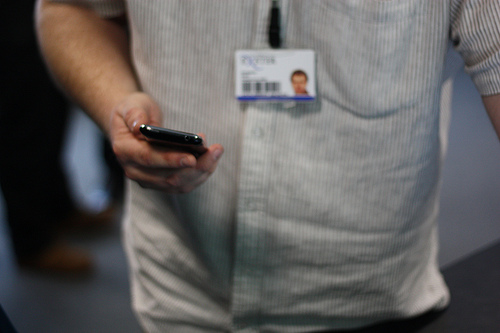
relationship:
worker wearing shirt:
[30, 0, 497, 329] [104, 1, 499, 330]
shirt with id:
[104, 1, 499, 330] [232, 49, 319, 102]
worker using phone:
[30, 0, 497, 329] [149, 90, 194, 171]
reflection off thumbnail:
[148, 107, 204, 133] [126, 118, 142, 133]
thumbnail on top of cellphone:
[126, 118, 142, 133] [125, 118, 210, 165]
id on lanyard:
[232, 49, 319, 102] [263, 1, 283, 50]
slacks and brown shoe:
[1, 1, 79, 256] [7, 240, 99, 282]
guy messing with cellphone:
[24, 6, 498, 325] [135, 121, 207, 157]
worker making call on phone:
[30, 0, 497, 329] [140, 124, 206, 158]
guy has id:
[32, 0, 500, 333] [232, 49, 319, 102]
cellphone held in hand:
[128, 124, 253, 184] [109, 92, 228, 193]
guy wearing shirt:
[32, 0, 500, 333] [104, 1, 499, 330]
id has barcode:
[230, 49, 318, 106] [237, 79, 280, 94]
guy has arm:
[32, 0, 500, 333] [35, 0, 145, 111]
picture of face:
[283, 64, 314, 99] [290, 70, 309, 98]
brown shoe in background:
[30, 241, 92, 281] [5, 194, 115, 331]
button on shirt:
[250, 126, 268, 144] [104, 1, 499, 330]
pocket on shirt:
[319, 11, 439, 129] [68, 3, 484, 330]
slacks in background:
[1, 1, 89, 258] [5, 6, 122, 330]